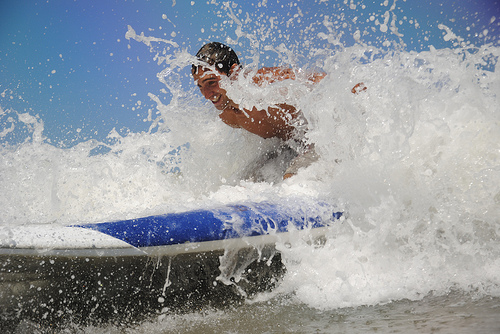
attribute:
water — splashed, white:
[3, 14, 498, 330]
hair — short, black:
[192, 39, 244, 74]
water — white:
[3, 49, 498, 331]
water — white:
[345, 75, 499, 242]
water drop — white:
[48, 67, 62, 80]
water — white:
[396, 181, 498, 236]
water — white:
[253, 267, 484, 332]